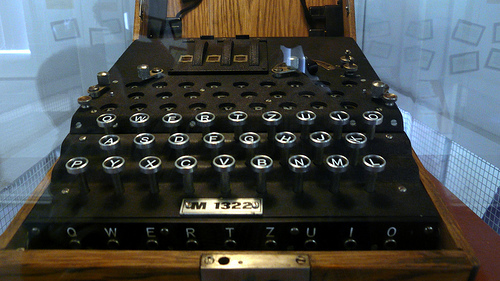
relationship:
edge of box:
[6, 245, 466, 268] [11, 17, 468, 262]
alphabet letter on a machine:
[64, 152, 88, 172] [3, 5, 480, 271]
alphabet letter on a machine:
[100, 153, 125, 174] [3, 5, 480, 271]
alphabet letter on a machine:
[360, 149, 389, 172] [3, 5, 480, 271]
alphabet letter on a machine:
[260, 222, 279, 244] [3, 5, 480, 271]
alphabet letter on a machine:
[381, 226, 404, 242] [38, 30, 444, 241]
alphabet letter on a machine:
[196, 104, 216, 126] [38, 30, 444, 241]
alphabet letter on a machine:
[238, 126, 264, 148] [38, 30, 444, 241]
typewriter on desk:
[33, 30, 445, 236] [10, 67, 484, 264]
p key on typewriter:
[65, 151, 92, 177] [33, 30, 445, 236]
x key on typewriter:
[140, 149, 161, 175] [33, 30, 445, 236]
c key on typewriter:
[170, 149, 198, 173] [33, 30, 445, 236]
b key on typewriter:
[247, 150, 278, 172] [33, 30, 445, 236]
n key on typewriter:
[288, 150, 318, 171] [33, 30, 445, 236]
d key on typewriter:
[167, 125, 192, 147] [33, 30, 445, 236]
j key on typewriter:
[306, 126, 333, 149] [33, 30, 445, 236]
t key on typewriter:
[227, 103, 253, 123] [33, 30, 445, 236]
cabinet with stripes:
[135, 5, 352, 38] [145, 10, 344, 33]